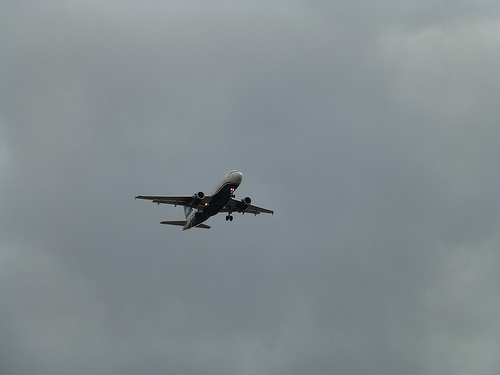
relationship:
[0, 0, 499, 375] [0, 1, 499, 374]
clouds in cloudy sky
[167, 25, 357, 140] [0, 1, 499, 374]
clouds in cloudy sky